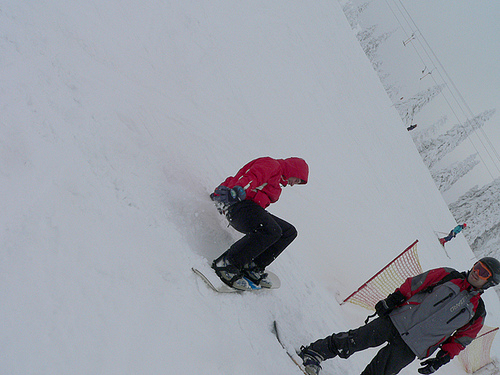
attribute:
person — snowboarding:
[209, 155, 312, 292]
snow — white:
[2, 2, 498, 375]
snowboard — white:
[189, 260, 284, 298]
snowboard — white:
[270, 318, 308, 373]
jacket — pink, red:
[224, 155, 311, 209]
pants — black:
[224, 197, 300, 274]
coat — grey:
[387, 266, 487, 361]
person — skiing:
[440, 223, 470, 250]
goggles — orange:
[472, 260, 491, 283]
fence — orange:
[336, 238, 500, 374]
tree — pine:
[414, 100, 498, 171]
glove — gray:
[209, 184, 248, 208]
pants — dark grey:
[308, 309, 415, 375]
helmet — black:
[476, 256, 499, 288]